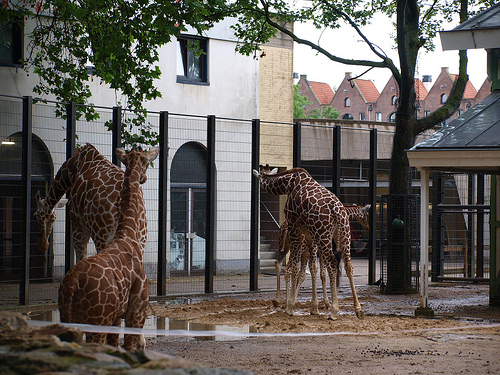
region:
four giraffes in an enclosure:
[22, 56, 372, 370]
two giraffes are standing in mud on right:
[245, 152, 378, 335]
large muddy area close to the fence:
[166, 285, 441, 330]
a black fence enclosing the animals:
[0, 81, 400, 301]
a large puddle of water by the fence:
[25, 305, 370, 350]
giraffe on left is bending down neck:
[0, 146, 115, 261]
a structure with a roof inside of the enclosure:
[405, 90, 495, 325]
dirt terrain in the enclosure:
[151, 321, 496, 371]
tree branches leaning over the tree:
[30, 67, 180, 167]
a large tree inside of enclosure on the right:
[381, 67, 469, 297]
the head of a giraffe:
[115, 136, 163, 182]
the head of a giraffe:
[116, 105, 183, 191]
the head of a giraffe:
[245, 155, 276, 195]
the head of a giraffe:
[31, 176, 71, 252]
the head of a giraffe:
[86, 140, 166, 201]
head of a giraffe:
[115, 132, 169, 192]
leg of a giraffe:
[350, 268, 382, 315]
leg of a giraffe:
[325, 253, 343, 312]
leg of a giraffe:
[320, 265, 333, 306]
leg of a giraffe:
[303, 275, 325, 322]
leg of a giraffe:
[288, 268, 310, 310]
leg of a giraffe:
[266, 254, 293, 310]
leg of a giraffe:
[86, 319, 119, 350]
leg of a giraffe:
[120, 302, 154, 347]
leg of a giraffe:
[105, 312, 132, 352]